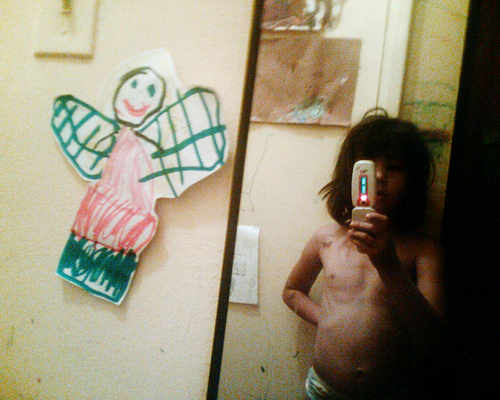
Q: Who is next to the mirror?
A: An angel.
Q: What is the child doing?
A: Taking a selfie.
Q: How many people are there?
A: One.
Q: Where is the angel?
A: Between the mirror and the lightswitch.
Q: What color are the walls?
A: White.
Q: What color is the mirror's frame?
A: Brown.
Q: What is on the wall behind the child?
A: Artwork.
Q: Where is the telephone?
A: In the child's left hand.